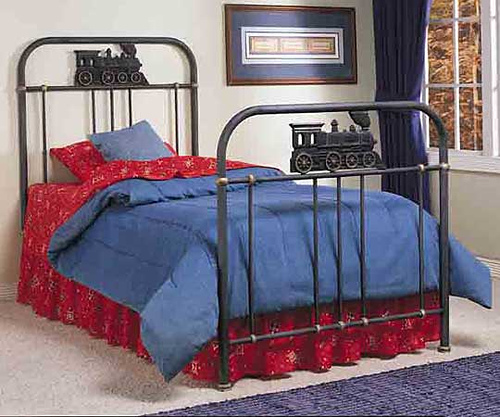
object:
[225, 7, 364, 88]
hanging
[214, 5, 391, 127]
wall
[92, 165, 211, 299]
comforter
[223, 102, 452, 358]
board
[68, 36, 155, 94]
engine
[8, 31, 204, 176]
headboard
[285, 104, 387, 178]
engine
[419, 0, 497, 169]
panes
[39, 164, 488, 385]
duvet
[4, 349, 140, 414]
floor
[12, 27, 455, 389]
bed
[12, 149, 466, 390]
mattress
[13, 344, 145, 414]
carpet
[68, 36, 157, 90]
train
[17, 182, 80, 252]
sheet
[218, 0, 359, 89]
picture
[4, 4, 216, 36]
wall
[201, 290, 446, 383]
red/bed skirt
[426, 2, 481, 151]
trees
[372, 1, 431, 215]
blue curtains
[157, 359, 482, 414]
blue rug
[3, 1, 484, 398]
bedroom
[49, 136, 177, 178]
red pillow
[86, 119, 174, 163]
blue pillow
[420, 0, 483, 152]
window